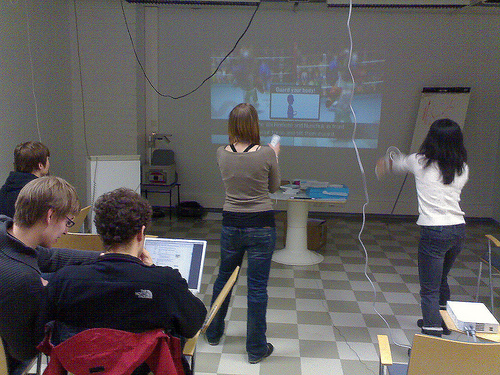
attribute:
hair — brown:
[227, 102, 262, 142]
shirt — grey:
[210, 139, 292, 227]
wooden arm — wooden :
[373, 327, 393, 373]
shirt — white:
[386, 150, 470, 225]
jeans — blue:
[219, 227, 271, 338]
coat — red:
[34, 309, 194, 374]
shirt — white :
[385, 110, 483, 232]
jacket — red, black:
[57, 238, 229, 351]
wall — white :
[70, 5, 497, 219]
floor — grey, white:
[324, 247, 404, 324]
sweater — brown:
[224, 145, 284, 202]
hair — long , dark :
[420, 113, 471, 195]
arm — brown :
[370, 315, 406, 372]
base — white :
[265, 192, 328, 271]